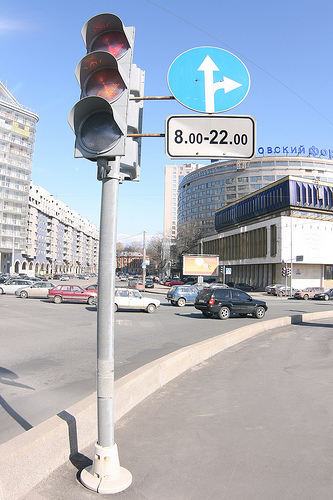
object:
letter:
[283, 146, 289, 153]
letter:
[298, 145, 305, 154]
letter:
[258, 147, 264, 154]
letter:
[267, 147, 272, 154]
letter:
[274, 146, 280, 153]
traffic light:
[67, 13, 145, 183]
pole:
[96, 178, 117, 446]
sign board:
[167, 45, 251, 114]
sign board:
[164, 113, 256, 159]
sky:
[0, 1, 332, 250]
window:
[225, 178, 232, 184]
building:
[177, 156, 333, 254]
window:
[206, 182, 209, 188]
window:
[263, 175, 275, 181]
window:
[249, 161, 261, 167]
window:
[302, 162, 314, 167]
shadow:
[0, 365, 94, 487]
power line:
[144, 0, 333, 126]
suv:
[194, 287, 268, 320]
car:
[47, 285, 98, 305]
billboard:
[182, 254, 219, 277]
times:
[175, 129, 248, 145]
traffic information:
[165, 45, 257, 160]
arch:
[13, 259, 21, 275]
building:
[0, 80, 116, 279]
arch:
[21, 260, 29, 273]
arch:
[45, 262, 51, 275]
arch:
[34, 261, 40, 277]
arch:
[55, 263, 59, 275]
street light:
[220, 265, 226, 284]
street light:
[282, 263, 292, 297]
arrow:
[197, 54, 220, 112]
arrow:
[213, 75, 243, 94]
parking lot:
[0, 270, 333, 444]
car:
[114, 288, 160, 314]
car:
[167, 285, 202, 307]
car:
[15, 281, 57, 299]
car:
[0, 278, 34, 295]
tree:
[146, 236, 166, 279]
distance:
[115, 236, 160, 276]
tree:
[123, 245, 134, 252]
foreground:
[0, 0, 333, 500]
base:
[79, 443, 134, 495]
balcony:
[18, 123, 25, 131]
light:
[88, 29, 130, 60]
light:
[83, 64, 128, 104]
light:
[79, 109, 123, 155]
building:
[196, 175, 333, 298]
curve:
[0, 309, 333, 499]